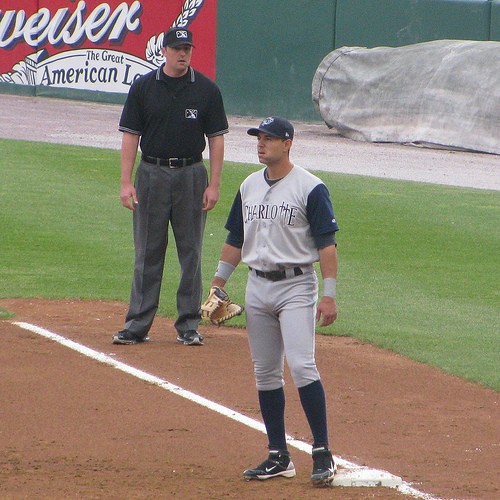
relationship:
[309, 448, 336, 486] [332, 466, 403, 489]
foot touching plate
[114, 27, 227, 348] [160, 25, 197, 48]
man wearing cap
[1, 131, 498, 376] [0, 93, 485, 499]
grass on field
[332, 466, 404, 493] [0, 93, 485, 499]
base on field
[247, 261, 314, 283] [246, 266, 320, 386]
belt on pants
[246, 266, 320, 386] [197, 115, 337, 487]
pants on player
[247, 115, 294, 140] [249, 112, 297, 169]
cap on head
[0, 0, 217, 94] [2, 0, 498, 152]
advertisement hanging on wall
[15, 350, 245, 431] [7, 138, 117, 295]
white stripe on field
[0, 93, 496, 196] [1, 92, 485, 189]
tan dirt on warning track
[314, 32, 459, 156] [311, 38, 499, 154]
canvas sleeve over canvas sleeve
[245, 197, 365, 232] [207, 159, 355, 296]
lettering on jersey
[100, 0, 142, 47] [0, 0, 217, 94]
white letter on a advertisement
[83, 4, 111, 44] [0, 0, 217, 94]
white letter on a advertisement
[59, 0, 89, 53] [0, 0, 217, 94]
white letter on a advertisement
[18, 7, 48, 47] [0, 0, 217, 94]
white letter on a advertisement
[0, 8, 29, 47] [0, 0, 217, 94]
white letter on a advertisement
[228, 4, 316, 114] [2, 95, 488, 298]
wall of outfield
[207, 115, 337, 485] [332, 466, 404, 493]
baseball player on base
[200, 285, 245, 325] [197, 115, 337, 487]
baseball glove on player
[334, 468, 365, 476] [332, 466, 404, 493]
dirt on base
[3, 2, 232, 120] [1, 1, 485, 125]
advertisement on wall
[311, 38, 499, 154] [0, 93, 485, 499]
canvas sleeve next to field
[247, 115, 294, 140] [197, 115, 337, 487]
cap on player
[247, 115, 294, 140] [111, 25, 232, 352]
cap on player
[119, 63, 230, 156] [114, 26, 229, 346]
shirt on umpire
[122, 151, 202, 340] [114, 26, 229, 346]
khakis on umpire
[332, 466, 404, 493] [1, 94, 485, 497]
base on baseball field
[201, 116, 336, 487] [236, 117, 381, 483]
man wearing uniform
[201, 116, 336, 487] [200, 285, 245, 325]
man wearing baseball glove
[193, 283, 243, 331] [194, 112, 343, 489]
baseball glove on man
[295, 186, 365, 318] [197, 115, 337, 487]
arm of player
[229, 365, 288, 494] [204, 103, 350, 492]
leg of player